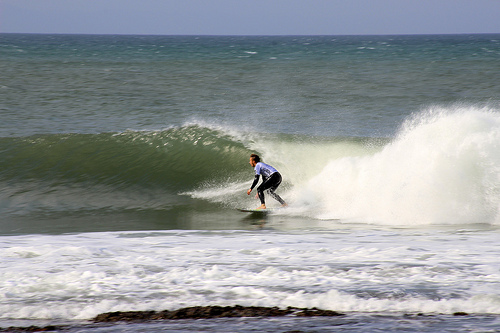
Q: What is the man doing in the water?
A: Surfing.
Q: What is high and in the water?
A: Wave.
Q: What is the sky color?
A: Blue.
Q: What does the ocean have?
A: Water.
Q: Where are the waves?
A: In the back.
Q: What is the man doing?
A: Surfing.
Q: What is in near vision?
A: Rocks.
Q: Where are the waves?
A: In the distance.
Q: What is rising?
A: Waves.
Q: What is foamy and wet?
A: Water.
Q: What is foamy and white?
A: Water.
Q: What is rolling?
A: Wave.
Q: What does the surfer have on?
A: A blue and black wetsuit.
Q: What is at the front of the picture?
A: Rocks.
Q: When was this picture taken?
A: Daytime.